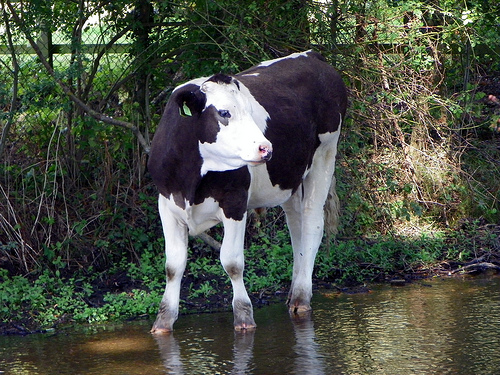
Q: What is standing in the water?
A: The cow.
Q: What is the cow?
A: Black and white.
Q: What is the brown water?
A: Shallow.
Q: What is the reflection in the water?
A: The cow.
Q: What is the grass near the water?
A: Short.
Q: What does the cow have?
A: The head.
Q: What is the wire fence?
A: Metal.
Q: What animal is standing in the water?
A: A cow.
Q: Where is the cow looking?
A: To its left.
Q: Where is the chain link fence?
A: Behind the trees.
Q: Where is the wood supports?
A: On the fence.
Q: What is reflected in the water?
A: The cow.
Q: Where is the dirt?
A: To the cow's right.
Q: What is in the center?
A: A cow.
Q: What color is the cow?
A: White and black.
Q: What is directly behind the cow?
A: A tree.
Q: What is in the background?
A: A fence.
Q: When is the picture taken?
A: Day time.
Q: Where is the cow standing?
A: In a stream.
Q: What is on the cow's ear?
A: A green tag.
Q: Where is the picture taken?
A: At a stream near a farm.